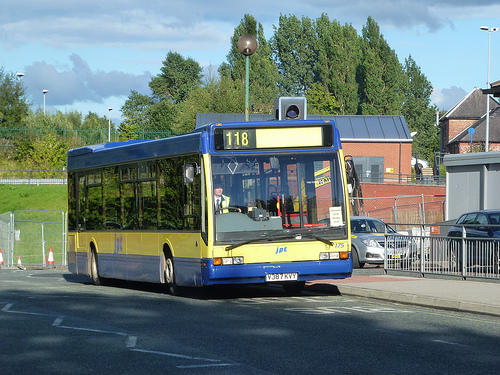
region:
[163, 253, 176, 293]
tire of the bus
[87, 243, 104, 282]
tire of the bus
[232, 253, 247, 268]
light on the bus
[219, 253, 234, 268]
light on the bus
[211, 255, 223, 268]
light on the bus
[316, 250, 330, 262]
light on the bus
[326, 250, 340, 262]
light on the bus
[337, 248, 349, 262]
light on the bus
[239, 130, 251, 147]
number on the bus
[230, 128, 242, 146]
number on the bus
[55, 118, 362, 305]
This is a bus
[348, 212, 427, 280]
This is a car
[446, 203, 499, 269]
This is a car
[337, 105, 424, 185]
This is a house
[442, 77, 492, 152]
This is a house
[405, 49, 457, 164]
This is a tree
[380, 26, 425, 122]
This is a tree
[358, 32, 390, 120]
This is a tree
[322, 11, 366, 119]
This is a tree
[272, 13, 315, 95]
This is a tree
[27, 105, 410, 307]
the bus is in motion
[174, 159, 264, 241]
bus driver is on the bus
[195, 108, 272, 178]
the numbers are yellow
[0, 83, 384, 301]
the bus is blue and yellow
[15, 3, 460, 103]
the sky is partly cloudy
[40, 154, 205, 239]
the trees reflected in the windows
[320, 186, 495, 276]
cars are parked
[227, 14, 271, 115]
a speaker on a pole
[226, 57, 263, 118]
the pole is green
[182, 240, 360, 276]
the headlights are off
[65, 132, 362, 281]
bus on the road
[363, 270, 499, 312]
sidewalk on the street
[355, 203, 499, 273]
vehicles to side of bus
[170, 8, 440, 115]
tree tops behind the buildings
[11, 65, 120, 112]
lights on the street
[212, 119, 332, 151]
number and route area for bus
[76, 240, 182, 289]
tires on the bus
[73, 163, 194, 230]
windows on the bus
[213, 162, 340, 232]
front window on the bus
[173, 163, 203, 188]
mirror on the bus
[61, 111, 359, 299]
yellow and blue bus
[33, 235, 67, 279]
orange and white traffic cone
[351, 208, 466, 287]
car near bicycle rack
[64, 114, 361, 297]
bus route number 118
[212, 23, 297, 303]
street light behind bus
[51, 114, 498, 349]
bus driving on street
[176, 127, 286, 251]
bus driver route 118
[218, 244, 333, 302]
license plate on bus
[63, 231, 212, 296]
wheels on yellow and blue bus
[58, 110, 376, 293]
passenger bus on route 118